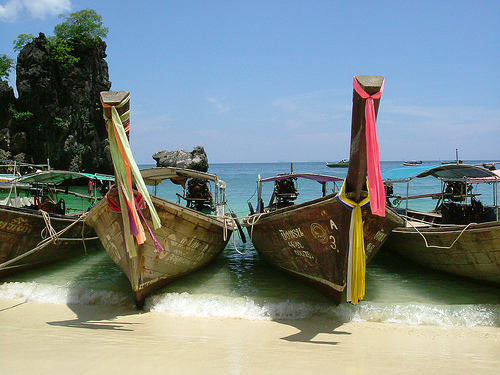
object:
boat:
[240, 76, 405, 305]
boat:
[0, 161, 116, 289]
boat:
[78, 89, 237, 310]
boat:
[378, 146, 499, 286]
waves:
[0, 159, 499, 322]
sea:
[0, 159, 499, 326]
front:
[304, 75, 401, 304]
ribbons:
[335, 177, 375, 306]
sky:
[0, 0, 499, 159]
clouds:
[0, 0, 27, 24]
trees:
[0, 54, 19, 79]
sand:
[0, 295, 499, 373]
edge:
[280, 334, 339, 345]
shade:
[271, 313, 353, 342]